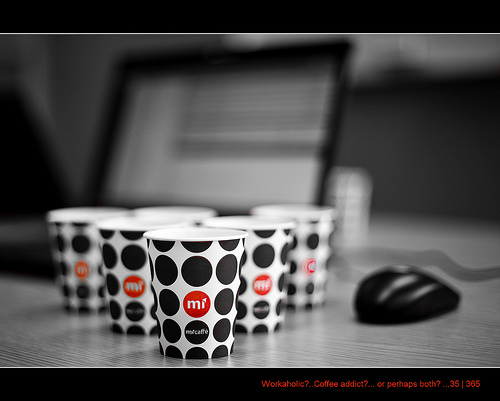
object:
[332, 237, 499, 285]
cable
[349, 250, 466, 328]
mouse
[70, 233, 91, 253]
dot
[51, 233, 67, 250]
dot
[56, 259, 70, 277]
dot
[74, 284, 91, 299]
dot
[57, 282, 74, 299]
dot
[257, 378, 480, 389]
text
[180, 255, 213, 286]
dots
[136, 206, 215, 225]
cup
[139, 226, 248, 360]
cup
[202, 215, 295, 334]
cup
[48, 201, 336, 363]
six polka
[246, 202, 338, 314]
cup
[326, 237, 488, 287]
cord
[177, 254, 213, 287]
polka dot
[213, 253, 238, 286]
polka dot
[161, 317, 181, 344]
polka dot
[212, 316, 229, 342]
polka dot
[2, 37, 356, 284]
laptop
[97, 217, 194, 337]
cup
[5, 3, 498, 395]
photograph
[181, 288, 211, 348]
coffee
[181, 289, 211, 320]
pattern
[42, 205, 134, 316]
cups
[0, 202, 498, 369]
desk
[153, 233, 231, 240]
interior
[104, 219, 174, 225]
interior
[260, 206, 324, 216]
interior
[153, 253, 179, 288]
dots